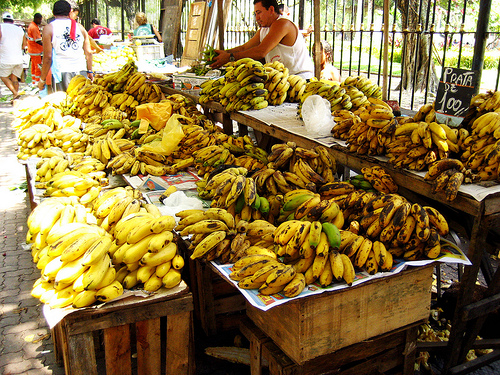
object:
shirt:
[0, 22, 24, 66]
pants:
[0, 63, 24, 79]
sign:
[436, 67, 474, 117]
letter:
[443, 68, 453, 83]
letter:
[450, 73, 457, 83]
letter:
[455, 74, 463, 86]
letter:
[465, 76, 473, 87]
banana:
[174, 208, 204, 214]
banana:
[135, 160, 170, 172]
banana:
[274, 147, 292, 165]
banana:
[369, 111, 392, 120]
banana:
[427, 121, 447, 143]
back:
[50, 18, 86, 59]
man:
[37, 0, 105, 92]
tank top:
[51, 20, 88, 73]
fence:
[178, 0, 496, 107]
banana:
[345, 96, 370, 105]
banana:
[275, 67, 290, 93]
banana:
[345, 77, 363, 88]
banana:
[248, 93, 264, 105]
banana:
[361, 135, 391, 145]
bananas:
[424, 157, 471, 200]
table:
[397, 164, 498, 217]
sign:
[60, 27, 81, 52]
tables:
[116, 166, 199, 227]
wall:
[160, 0, 209, 65]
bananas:
[405, 210, 432, 255]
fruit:
[184, 217, 267, 247]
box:
[173, 70, 225, 97]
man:
[87, 19, 114, 39]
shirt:
[88, 26, 115, 39]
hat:
[90, 18, 101, 25]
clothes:
[27, 20, 43, 87]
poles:
[316, 3, 474, 66]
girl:
[312, 41, 341, 83]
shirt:
[321, 63, 340, 82]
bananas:
[24, 102, 45, 124]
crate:
[246, 261, 434, 366]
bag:
[301, 94, 336, 138]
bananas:
[65, 78, 94, 96]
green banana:
[322, 222, 341, 250]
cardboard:
[171, 69, 225, 97]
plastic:
[301, 95, 337, 136]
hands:
[207, 49, 231, 70]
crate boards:
[53, 280, 192, 375]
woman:
[132, 11, 162, 42]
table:
[20, 275, 200, 373]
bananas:
[132, 254, 171, 287]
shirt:
[260, 17, 315, 80]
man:
[207, 0, 315, 83]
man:
[0, 13, 27, 99]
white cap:
[1, 12, 14, 19]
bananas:
[73, 274, 110, 305]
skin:
[313, 192, 348, 211]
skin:
[377, 199, 407, 227]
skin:
[288, 190, 324, 201]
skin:
[419, 204, 449, 235]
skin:
[281, 222, 332, 244]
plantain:
[31, 271, 84, 306]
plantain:
[142, 271, 164, 292]